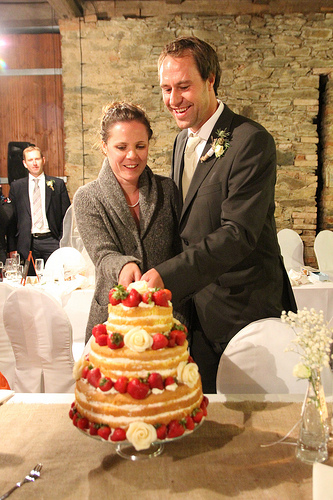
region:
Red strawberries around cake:
[82, 345, 175, 415]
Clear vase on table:
[296, 371, 330, 469]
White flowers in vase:
[268, 308, 307, 370]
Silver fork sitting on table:
[18, 449, 55, 499]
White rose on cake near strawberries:
[127, 405, 162, 483]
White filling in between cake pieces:
[102, 350, 151, 389]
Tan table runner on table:
[33, 413, 332, 498]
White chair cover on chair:
[216, 320, 273, 389]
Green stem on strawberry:
[98, 372, 113, 415]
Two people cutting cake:
[83, 91, 259, 262]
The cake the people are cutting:
[60, 270, 208, 451]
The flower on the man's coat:
[199, 129, 231, 163]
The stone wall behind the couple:
[56, 0, 331, 273]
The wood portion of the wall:
[0, 29, 66, 218]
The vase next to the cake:
[294, 370, 332, 466]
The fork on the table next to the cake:
[2, 461, 48, 498]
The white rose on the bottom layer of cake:
[127, 421, 154, 453]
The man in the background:
[9, 148, 72, 261]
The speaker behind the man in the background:
[7, 139, 37, 185]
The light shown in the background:
[0, 39, 17, 75]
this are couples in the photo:
[83, 35, 300, 278]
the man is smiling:
[158, 33, 272, 159]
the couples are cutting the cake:
[73, 43, 263, 432]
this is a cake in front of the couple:
[67, 286, 205, 443]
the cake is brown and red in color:
[71, 289, 203, 437]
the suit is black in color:
[210, 133, 270, 317]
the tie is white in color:
[187, 137, 199, 165]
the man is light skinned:
[168, 57, 191, 78]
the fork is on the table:
[0, 458, 47, 492]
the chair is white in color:
[0, 284, 71, 366]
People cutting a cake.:
[54, 39, 314, 431]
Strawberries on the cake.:
[81, 339, 328, 414]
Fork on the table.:
[2, 448, 83, 498]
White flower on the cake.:
[117, 423, 201, 456]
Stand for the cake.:
[88, 419, 209, 470]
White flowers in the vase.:
[278, 305, 330, 432]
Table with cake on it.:
[214, 389, 300, 498]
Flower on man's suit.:
[203, 133, 261, 186]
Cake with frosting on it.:
[76, 345, 179, 389]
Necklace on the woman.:
[97, 174, 158, 219]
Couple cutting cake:
[44, 10, 330, 439]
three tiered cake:
[50, 275, 215, 461]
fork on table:
[4, 446, 59, 499]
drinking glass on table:
[29, 252, 51, 287]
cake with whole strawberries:
[62, 272, 224, 449]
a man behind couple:
[0, 123, 63, 278]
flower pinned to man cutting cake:
[191, 121, 230, 172]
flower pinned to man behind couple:
[8, 137, 57, 192]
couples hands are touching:
[103, 250, 180, 307]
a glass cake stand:
[65, 414, 225, 463]